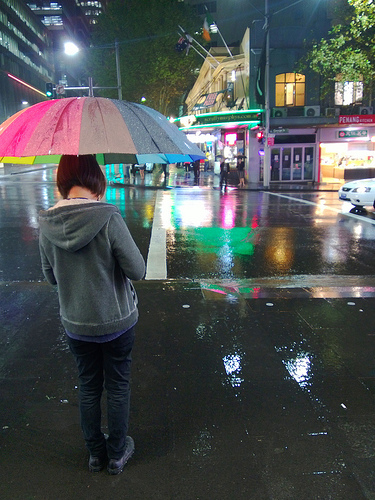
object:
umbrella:
[0, 93, 206, 165]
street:
[0, 167, 375, 500]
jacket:
[38, 197, 147, 335]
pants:
[66, 326, 135, 461]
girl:
[38, 154, 146, 474]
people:
[219, 156, 231, 191]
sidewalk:
[0, 167, 375, 500]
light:
[62, 39, 81, 58]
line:
[144, 181, 171, 281]